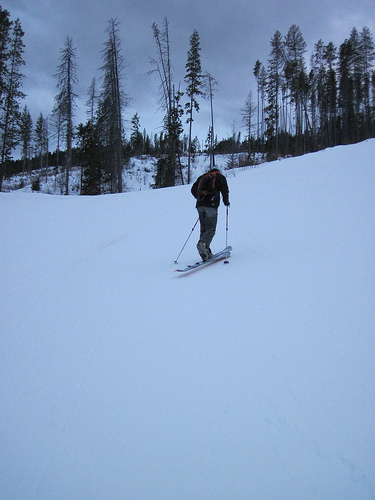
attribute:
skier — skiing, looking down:
[174, 158, 238, 268]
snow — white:
[272, 163, 372, 247]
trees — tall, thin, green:
[239, 22, 375, 163]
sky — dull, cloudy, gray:
[1, 2, 373, 168]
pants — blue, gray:
[193, 206, 222, 259]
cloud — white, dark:
[33, 88, 147, 134]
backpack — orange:
[193, 172, 220, 201]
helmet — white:
[210, 166, 220, 170]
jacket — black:
[191, 174, 230, 210]